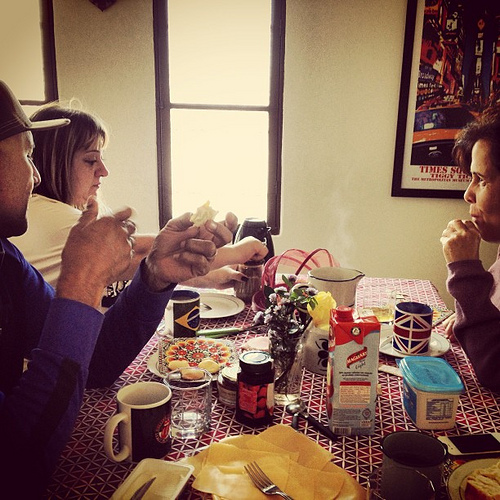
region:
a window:
[165, 2, 270, 224]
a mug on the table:
[111, 383, 178, 459]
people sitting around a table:
[2, 83, 499, 407]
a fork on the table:
[241, 459, 293, 499]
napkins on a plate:
[208, 436, 335, 498]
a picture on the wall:
[407, 3, 496, 198]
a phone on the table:
[437, 427, 499, 462]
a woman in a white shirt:
[19, 105, 139, 281]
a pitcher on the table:
[311, 265, 363, 307]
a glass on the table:
[163, 368, 207, 434]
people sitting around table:
[3, 56, 498, 498]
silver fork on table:
[220, 440, 302, 498]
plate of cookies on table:
[130, 315, 245, 395]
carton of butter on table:
[389, 352, 476, 445]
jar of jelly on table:
[219, 321, 299, 433]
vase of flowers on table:
[249, 265, 337, 415]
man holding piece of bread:
[143, 198, 246, 304]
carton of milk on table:
[315, 295, 400, 438]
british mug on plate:
[380, 278, 444, 362]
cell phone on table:
[427, 410, 498, 467]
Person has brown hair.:
[59, 136, 79, 161]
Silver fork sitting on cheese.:
[237, 453, 284, 493]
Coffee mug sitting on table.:
[108, 385, 210, 474]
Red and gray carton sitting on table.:
[326, 316, 385, 432]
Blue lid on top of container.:
[389, 345, 463, 399]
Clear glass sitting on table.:
[167, 368, 231, 443]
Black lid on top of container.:
[240, 346, 281, 372]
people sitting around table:
[4, 64, 499, 489]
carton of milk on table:
[312, 280, 402, 467]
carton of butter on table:
[387, 332, 469, 456]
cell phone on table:
[416, 399, 498, 472]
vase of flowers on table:
[240, 238, 336, 413]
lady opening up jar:
[143, 185, 268, 314]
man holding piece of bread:
[118, 158, 299, 296]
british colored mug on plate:
[370, 262, 442, 384]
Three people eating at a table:
[0, 77, 497, 487]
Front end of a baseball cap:
[0, 76, 71, 136]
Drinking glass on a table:
[164, 367, 212, 438]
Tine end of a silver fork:
[243, 459, 296, 498]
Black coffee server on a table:
[230, 216, 276, 305]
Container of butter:
[398, 353, 466, 432]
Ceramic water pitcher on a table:
[301, 263, 365, 375]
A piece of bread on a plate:
[445, 456, 499, 497]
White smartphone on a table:
[436, 431, 498, 459]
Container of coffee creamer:
[325, 305, 381, 437]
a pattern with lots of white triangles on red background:
[341, 438, 381, 477]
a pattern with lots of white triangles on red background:
[66, 464, 118, 499]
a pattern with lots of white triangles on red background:
[73, 426, 110, 464]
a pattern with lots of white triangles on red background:
[83, 394, 120, 425]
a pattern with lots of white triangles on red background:
[128, 360, 151, 384]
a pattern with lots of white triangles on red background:
[468, 405, 499, 430]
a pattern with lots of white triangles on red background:
[446, 350, 472, 380]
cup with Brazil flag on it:
[152, 280, 207, 341]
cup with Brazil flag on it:
[154, 285, 224, 355]